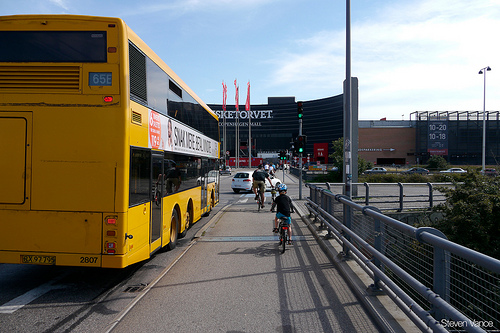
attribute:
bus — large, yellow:
[0, 15, 218, 267]